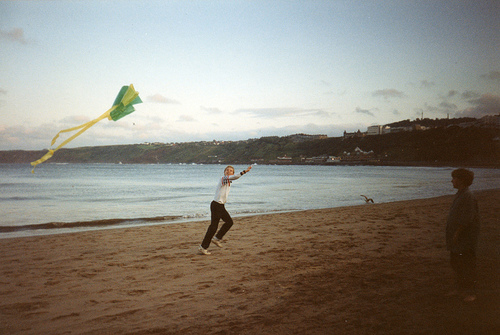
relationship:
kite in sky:
[28, 84, 141, 173] [2, 1, 499, 150]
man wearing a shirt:
[198, 162, 264, 256] [211, 168, 248, 206]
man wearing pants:
[198, 162, 264, 256] [200, 200, 234, 249]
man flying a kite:
[198, 162, 264, 256] [28, 84, 141, 173]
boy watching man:
[442, 168, 482, 303] [198, 162, 264, 256]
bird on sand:
[359, 191, 377, 206] [0, 187, 498, 334]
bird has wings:
[359, 191, 377, 206] [360, 195, 378, 202]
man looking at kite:
[198, 162, 264, 256] [28, 84, 141, 173]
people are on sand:
[200, 161, 482, 305] [0, 187, 498, 334]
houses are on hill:
[143, 114, 497, 167] [0, 113, 498, 165]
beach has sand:
[0, 187, 498, 333] [0, 187, 498, 334]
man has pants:
[198, 162, 264, 256] [200, 200, 234, 249]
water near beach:
[1, 162, 499, 238] [0, 187, 498, 333]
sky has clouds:
[2, 1, 499, 150] [0, 22, 499, 150]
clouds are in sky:
[0, 22, 499, 150] [2, 1, 499, 150]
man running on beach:
[198, 162, 264, 256] [0, 187, 498, 333]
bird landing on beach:
[359, 191, 377, 206] [0, 187, 498, 333]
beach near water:
[0, 187, 498, 333] [1, 162, 499, 238]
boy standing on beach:
[442, 168, 482, 303] [0, 187, 498, 333]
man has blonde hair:
[198, 162, 264, 256] [222, 166, 234, 173]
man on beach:
[198, 162, 264, 256] [0, 187, 498, 333]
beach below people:
[0, 187, 498, 333] [200, 161, 482, 305]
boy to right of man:
[442, 168, 482, 303] [198, 162, 264, 256]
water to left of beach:
[1, 162, 499, 238] [0, 187, 498, 333]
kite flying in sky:
[28, 84, 141, 173] [2, 1, 499, 150]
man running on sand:
[198, 162, 264, 256] [0, 187, 498, 334]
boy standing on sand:
[442, 168, 482, 303] [0, 187, 498, 334]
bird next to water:
[359, 191, 377, 206] [1, 162, 499, 238]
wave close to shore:
[1, 207, 308, 233] [2, 185, 500, 243]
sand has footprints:
[0, 187, 498, 334] [7, 189, 500, 329]